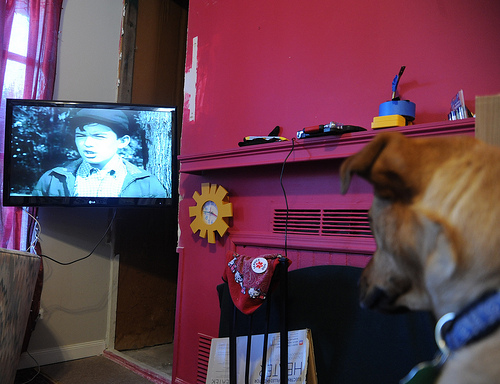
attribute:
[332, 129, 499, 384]
dog — brown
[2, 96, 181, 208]
television — flatscreen, mounted, black, white, large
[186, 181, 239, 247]
clock — yellow, flower, white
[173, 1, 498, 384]
wall — red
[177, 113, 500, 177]
mantle — pink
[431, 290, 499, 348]
collar — black, blue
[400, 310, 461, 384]
ring — silver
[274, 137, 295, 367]
cord — black, long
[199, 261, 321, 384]
bag — white, black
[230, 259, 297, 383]
straps — black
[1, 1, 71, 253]
curtains — pink, red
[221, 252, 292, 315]
bandana — red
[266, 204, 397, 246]
grates — red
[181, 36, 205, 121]
patch — white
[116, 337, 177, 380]
floor — whtie, white